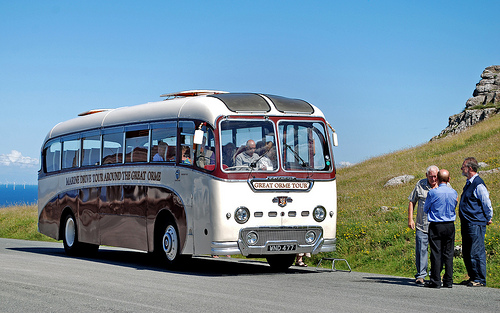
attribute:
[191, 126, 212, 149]
mirror — side view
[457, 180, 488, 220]
vest — blue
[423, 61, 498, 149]
mountain peak — far distant, snowy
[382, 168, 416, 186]
rocks — big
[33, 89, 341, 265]
bus — vintage, white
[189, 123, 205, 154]
mirror — white, side mirror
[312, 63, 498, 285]
hill — gently sloping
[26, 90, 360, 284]
tour bus — reddish brown, white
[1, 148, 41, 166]
peak — mountain